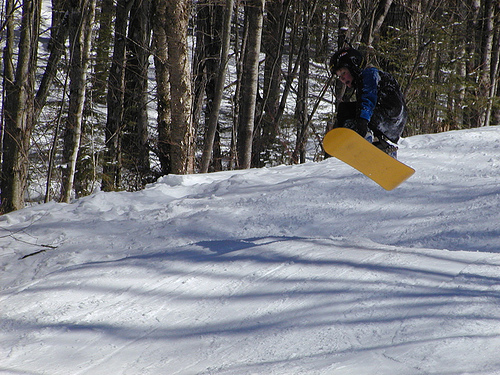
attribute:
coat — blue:
[329, 67, 411, 142]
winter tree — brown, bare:
[154, 19, 200, 165]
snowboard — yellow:
[322, 128, 414, 191]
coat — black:
[347, 66, 412, 135]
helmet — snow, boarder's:
[324, 44, 364, 77]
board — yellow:
[322, 121, 416, 196]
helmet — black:
[330, 50, 360, 75]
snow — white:
[0, 124, 497, 371]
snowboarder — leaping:
[324, 40, 413, 156]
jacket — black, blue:
[338, 67, 403, 140]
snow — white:
[105, 211, 467, 363]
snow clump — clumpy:
[179, 180, 224, 202]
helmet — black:
[306, 40, 403, 92]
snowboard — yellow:
[326, 120, 468, 212]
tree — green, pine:
[236, 0, 263, 168]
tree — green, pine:
[161, 1, 194, 173]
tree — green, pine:
[121, 0, 155, 188]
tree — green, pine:
[60, 1, 95, 201]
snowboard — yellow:
[321, 127, 414, 186]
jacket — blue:
[354, 62, 390, 122]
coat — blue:
[344, 70, 405, 140]